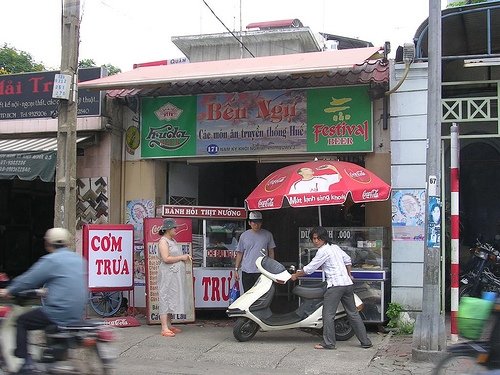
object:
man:
[1, 227, 88, 375]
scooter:
[0, 287, 119, 374]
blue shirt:
[7, 246, 89, 326]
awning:
[0, 135, 94, 183]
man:
[289, 226, 373, 349]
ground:
[389, 71, 450, 327]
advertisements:
[139, 84, 375, 159]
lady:
[157, 217, 193, 337]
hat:
[248, 211, 263, 222]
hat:
[44, 227, 73, 245]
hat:
[160, 218, 180, 230]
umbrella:
[243, 158, 392, 226]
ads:
[286, 164, 345, 205]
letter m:
[111, 236, 123, 252]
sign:
[80, 224, 136, 292]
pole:
[450, 121, 461, 342]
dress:
[157, 236, 190, 316]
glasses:
[250, 221, 262, 225]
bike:
[224, 249, 365, 343]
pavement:
[145, 337, 291, 375]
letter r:
[103, 259, 111, 275]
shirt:
[302, 242, 352, 289]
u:
[112, 259, 121, 275]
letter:
[89, 229, 133, 287]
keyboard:
[407, 101, 439, 368]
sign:
[120, 84, 374, 161]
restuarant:
[75, 48, 392, 329]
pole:
[421, 0, 446, 353]